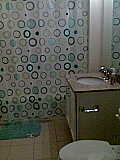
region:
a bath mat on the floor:
[0, 121, 41, 139]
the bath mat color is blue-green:
[0, 121, 41, 139]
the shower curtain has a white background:
[0, 1, 88, 122]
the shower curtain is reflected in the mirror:
[112, 0, 119, 70]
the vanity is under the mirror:
[67, 74, 119, 140]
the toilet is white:
[57, 138, 119, 157]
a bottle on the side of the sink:
[111, 68, 115, 84]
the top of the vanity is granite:
[66, 74, 117, 89]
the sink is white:
[77, 76, 105, 84]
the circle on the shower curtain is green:
[54, 63, 62, 70]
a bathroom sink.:
[72, 72, 110, 89]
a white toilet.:
[49, 134, 119, 158]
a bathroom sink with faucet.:
[61, 58, 118, 145]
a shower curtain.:
[0, 1, 90, 123]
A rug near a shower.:
[0, 118, 44, 139]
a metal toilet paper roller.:
[80, 100, 103, 114]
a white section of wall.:
[87, 0, 112, 73]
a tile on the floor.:
[8, 140, 35, 154]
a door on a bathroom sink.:
[67, 90, 76, 136]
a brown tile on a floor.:
[10, 135, 36, 146]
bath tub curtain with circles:
[1, 2, 91, 122]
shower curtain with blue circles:
[3, 5, 93, 125]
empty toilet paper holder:
[79, 102, 99, 118]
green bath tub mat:
[0, 122, 44, 142]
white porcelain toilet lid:
[53, 131, 117, 159]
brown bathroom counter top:
[64, 67, 118, 97]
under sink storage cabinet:
[61, 74, 82, 140]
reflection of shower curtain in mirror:
[108, 0, 119, 68]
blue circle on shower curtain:
[27, 37, 39, 49]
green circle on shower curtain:
[16, 103, 24, 112]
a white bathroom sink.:
[74, 72, 106, 89]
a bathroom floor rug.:
[0, 115, 45, 143]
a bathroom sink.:
[61, 65, 119, 143]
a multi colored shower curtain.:
[0, 0, 87, 124]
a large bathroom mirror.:
[103, 1, 119, 70]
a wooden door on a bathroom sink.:
[64, 87, 77, 136]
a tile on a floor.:
[30, 134, 57, 148]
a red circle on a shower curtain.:
[27, 93, 35, 103]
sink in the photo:
[76, 64, 113, 90]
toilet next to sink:
[56, 138, 104, 159]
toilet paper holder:
[77, 103, 100, 118]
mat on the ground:
[6, 120, 44, 144]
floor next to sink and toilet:
[16, 136, 56, 157]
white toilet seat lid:
[79, 144, 94, 153]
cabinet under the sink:
[56, 85, 77, 104]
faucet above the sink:
[95, 65, 108, 72]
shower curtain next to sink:
[8, 44, 49, 76]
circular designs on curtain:
[18, 51, 49, 78]